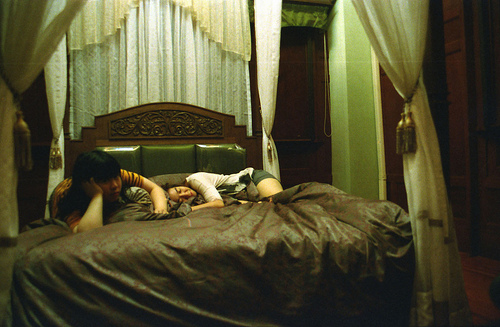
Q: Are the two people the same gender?
A: No, they are both male and female.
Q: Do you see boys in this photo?
A: No, there are no boys.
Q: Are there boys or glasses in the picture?
A: No, there are no boys or glasses.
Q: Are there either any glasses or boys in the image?
A: No, there are no boys or glasses.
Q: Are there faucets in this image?
A: No, there are no faucets.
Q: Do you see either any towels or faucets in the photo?
A: No, there are no faucets or towels.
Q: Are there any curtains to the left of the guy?
A: Yes, there is a curtain to the left of the guy.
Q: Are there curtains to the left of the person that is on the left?
A: Yes, there is a curtain to the left of the guy.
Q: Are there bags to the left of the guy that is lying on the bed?
A: No, there is a curtain to the left of the guy.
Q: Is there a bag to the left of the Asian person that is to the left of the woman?
A: No, there is a curtain to the left of the guy.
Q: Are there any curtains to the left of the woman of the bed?
A: Yes, there is a curtain to the left of the woman.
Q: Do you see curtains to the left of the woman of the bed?
A: Yes, there is a curtain to the left of the woman.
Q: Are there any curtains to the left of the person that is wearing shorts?
A: Yes, there is a curtain to the left of the woman.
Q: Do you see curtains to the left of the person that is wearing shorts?
A: Yes, there is a curtain to the left of the woman.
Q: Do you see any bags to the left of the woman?
A: No, there is a curtain to the left of the woman.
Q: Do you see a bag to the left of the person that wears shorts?
A: No, there is a curtain to the left of the woman.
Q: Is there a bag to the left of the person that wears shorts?
A: No, there is a curtain to the left of the woman.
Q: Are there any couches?
A: No, there are no couches.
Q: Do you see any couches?
A: No, there are no couches.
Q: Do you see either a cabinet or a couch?
A: No, there are no couches or cabinets.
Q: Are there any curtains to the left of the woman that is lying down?
A: Yes, there is a curtain to the left of the woman.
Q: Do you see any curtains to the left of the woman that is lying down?
A: Yes, there is a curtain to the left of the woman.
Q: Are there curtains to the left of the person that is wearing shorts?
A: Yes, there is a curtain to the left of the woman.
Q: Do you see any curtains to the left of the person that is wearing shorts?
A: Yes, there is a curtain to the left of the woman.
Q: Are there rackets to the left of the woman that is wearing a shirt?
A: No, there is a curtain to the left of the woman.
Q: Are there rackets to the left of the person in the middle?
A: No, there is a curtain to the left of the woman.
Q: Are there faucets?
A: No, there are no faucets.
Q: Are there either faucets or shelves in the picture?
A: No, there are no faucets or shelves.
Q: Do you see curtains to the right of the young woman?
A: Yes, there is a curtain to the right of the woman.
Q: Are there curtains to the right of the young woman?
A: Yes, there is a curtain to the right of the woman.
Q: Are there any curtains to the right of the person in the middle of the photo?
A: Yes, there is a curtain to the right of the woman.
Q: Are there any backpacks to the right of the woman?
A: No, there is a curtain to the right of the woman.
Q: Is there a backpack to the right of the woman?
A: No, there is a curtain to the right of the woman.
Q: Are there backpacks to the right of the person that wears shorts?
A: No, there is a curtain to the right of the woman.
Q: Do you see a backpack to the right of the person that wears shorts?
A: No, there is a curtain to the right of the woman.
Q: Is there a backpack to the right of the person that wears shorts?
A: No, there is a curtain to the right of the woman.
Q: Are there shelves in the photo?
A: No, there are no shelves.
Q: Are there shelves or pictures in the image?
A: No, there are no shelves or pictures.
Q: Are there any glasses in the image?
A: No, there are no glasses.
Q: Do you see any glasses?
A: No, there are no glasses.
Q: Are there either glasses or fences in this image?
A: No, there are no glasses or fences.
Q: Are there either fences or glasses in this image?
A: No, there are no glasses or fences.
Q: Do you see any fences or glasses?
A: No, there are no glasses or fences.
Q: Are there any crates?
A: No, there are no crates.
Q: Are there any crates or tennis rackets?
A: No, there are no crates or tennis rackets.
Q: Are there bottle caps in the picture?
A: No, there are no bottle caps.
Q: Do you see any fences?
A: No, there are no fences.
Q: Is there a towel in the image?
A: No, there are no towels.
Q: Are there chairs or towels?
A: No, there are no towels or chairs.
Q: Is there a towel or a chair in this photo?
A: No, there are no towels or chairs.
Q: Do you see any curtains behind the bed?
A: Yes, there is a curtain behind the bed.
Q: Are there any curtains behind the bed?
A: Yes, there is a curtain behind the bed.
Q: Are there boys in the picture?
A: No, there are no boys.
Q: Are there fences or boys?
A: No, there are no boys or fences.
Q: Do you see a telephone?
A: No, there are no phones.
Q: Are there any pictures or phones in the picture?
A: No, there are no phones or pictures.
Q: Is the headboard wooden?
A: Yes, the headboard is wooden.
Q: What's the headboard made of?
A: The headboard is made of wood.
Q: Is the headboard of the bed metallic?
A: No, the headboard is wooden.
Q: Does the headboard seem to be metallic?
A: No, the headboard is wooden.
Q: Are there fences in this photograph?
A: No, there are no fences.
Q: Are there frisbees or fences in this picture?
A: No, there are no fences or frisbees.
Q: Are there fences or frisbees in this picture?
A: No, there are no fences or frisbees.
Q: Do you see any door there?
A: Yes, there is a door.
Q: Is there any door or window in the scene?
A: Yes, there is a door.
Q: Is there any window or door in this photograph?
A: Yes, there is a door.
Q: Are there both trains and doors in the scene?
A: No, there is a door but no trains.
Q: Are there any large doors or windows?
A: Yes, there is a large door.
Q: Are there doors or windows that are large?
A: Yes, the door is large.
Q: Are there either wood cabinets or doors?
A: Yes, there is a wood door.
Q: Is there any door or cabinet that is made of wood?
A: Yes, the door is made of wood.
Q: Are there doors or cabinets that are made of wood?
A: Yes, the door is made of wood.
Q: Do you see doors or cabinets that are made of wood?
A: Yes, the door is made of wood.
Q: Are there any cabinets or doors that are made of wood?
A: Yes, the door is made of wood.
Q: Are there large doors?
A: Yes, there is a large door.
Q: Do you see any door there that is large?
A: Yes, there is a door that is large.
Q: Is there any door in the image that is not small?
A: Yes, there is a large door.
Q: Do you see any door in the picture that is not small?
A: Yes, there is a large door.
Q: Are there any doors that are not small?
A: Yes, there is a large door.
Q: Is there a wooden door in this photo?
A: Yes, there is a wood door.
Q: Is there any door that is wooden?
A: Yes, there is a door that is wooden.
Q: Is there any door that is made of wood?
A: Yes, there is a door that is made of wood.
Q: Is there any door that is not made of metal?
A: Yes, there is a door that is made of wood.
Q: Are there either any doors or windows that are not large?
A: No, there is a door but it is large.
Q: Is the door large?
A: Yes, the door is large.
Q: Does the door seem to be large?
A: Yes, the door is large.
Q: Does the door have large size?
A: Yes, the door is large.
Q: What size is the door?
A: The door is large.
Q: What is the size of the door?
A: The door is large.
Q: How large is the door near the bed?
A: The door is large.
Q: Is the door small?
A: No, the door is large.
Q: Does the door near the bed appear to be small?
A: No, the door is large.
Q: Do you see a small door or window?
A: No, there is a door but it is large.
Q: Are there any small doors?
A: No, there is a door but it is large.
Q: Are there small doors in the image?
A: No, there is a door but it is large.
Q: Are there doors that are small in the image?
A: No, there is a door but it is large.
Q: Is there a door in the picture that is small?
A: No, there is a door but it is large.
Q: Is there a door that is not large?
A: No, there is a door but it is large.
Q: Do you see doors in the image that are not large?
A: No, there is a door but it is large.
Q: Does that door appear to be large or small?
A: The door is large.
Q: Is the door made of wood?
A: Yes, the door is made of wood.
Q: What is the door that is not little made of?
A: The door is made of wood.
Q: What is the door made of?
A: The door is made of wood.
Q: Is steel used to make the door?
A: No, the door is made of wood.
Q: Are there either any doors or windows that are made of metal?
A: No, there is a door but it is made of wood.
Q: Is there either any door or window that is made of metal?
A: No, there is a door but it is made of wood.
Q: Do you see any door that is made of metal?
A: No, there is a door but it is made of wood.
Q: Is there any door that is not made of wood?
A: No, there is a door but it is made of wood.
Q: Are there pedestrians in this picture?
A: No, there are no pedestrians.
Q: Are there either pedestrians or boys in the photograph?
A: No, there are no pedestrians or boys.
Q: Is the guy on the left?
A: Yes, the guy is on the left of the image.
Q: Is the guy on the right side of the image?
A: No, the guy is on the left of the image.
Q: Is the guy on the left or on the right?
A: The guy is on the left of the image.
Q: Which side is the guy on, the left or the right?
A: The guy is on the left of the image.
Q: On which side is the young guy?
A: The guy is on the left of the image.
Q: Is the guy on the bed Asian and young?
A: Yes, the guy is Asian and young.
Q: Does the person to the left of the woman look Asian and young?
A: Yes, the guy is Asian and young.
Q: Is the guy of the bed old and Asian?
A: No, the guy is Asian but young.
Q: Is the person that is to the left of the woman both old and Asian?
A: No, the guy is Asian but young.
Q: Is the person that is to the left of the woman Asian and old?
A: No, the guy is Asian but young.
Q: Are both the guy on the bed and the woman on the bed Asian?
A: Yes, both the guy and the woman are asian.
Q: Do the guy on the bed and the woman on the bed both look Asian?
A: Yes, both the guy and the woman are asian.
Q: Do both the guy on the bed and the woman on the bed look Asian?
A: Yes, both the guy and the woman are asian.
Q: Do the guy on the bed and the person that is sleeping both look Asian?
A: Yes, both the guy and the woman are asian.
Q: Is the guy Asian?
A: Yes, the guy is asian.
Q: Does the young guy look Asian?
A: Yes, the guy is asian.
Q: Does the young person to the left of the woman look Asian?
A: Yes, the guy is asian.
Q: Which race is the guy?
A: The guy is asian.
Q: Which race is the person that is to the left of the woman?
A: The guy is asian.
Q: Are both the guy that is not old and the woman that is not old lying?
A: Yes, both the guy and the woman are lying.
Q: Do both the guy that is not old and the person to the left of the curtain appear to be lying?
A: Yes, both the guy and the woman are lying.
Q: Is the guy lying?
A: Yes, the guy is lying.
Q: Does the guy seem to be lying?
A: Yes, the guy is lying.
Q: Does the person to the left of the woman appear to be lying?
A: Yes, the guy is lying.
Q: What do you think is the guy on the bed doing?
A: The guy is lying.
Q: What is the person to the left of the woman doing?
A: The guy is lying.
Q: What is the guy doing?
A: The guy is lying.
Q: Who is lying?
A: The guy is lying.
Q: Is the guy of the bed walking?
A: No, the guy is lying.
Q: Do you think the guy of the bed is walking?
A: No, the guy is lying.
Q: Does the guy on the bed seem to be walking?
A: No, the guy is lying.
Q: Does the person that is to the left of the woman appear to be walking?
A: No, the guy is lying.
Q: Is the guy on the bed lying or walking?
A: The guy is lying.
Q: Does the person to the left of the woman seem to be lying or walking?
A: The guy is lying.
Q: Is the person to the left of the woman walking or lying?
A: The guy is lying.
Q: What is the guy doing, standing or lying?
A: The guy is lying.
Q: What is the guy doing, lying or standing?
A: The guy is lying.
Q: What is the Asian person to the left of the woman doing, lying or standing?
A: The guy is lying.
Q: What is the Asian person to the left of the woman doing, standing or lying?
A: The guy is lying.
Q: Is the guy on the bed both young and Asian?
A: Yes, the guy is young and asian.